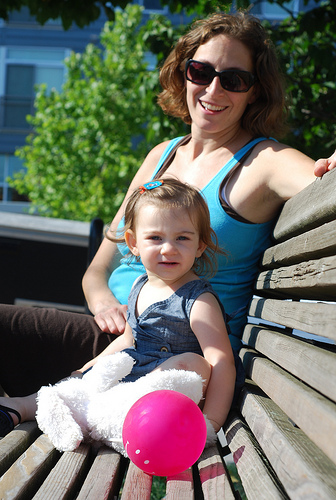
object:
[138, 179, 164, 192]
barrette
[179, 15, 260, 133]
head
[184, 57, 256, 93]
glasses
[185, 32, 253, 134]
face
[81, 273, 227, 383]
dress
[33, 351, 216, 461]
animal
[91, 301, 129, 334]
hand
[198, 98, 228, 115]
mouth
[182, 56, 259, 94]
sunglasses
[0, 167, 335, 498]
bench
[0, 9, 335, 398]
woman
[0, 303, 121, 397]
pants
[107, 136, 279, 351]
tank top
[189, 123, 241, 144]
neck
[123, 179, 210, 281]
head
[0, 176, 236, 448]
baby girl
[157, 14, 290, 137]
dark hair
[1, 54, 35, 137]
window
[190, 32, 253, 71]
forehead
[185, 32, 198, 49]
hair brush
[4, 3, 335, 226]
tree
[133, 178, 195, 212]
top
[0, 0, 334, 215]
building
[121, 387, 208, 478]
balloon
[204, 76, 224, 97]
nose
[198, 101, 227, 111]
teeth